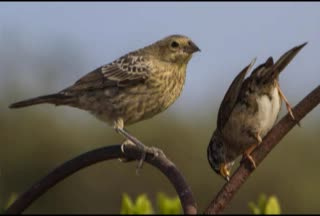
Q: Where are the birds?
A: On a branch.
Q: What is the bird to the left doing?
A: Looking towards the left.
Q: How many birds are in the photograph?
A: Two.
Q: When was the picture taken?
A: Daytime.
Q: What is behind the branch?
A: A plant.